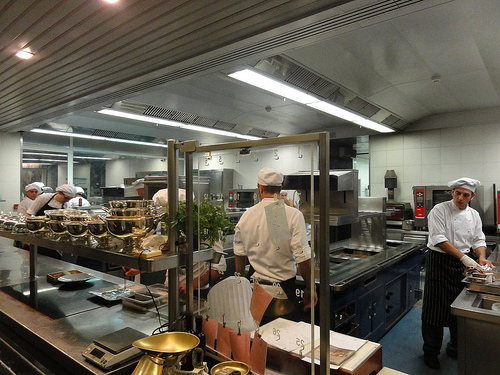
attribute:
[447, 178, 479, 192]
hat — round, white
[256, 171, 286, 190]
hat — round, white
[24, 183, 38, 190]
hat — round, white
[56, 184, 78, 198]
hat — round, white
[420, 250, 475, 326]
apron — striped, black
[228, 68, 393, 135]
light — on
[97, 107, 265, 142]
light — on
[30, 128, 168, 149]
light — on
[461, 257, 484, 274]
glove — white